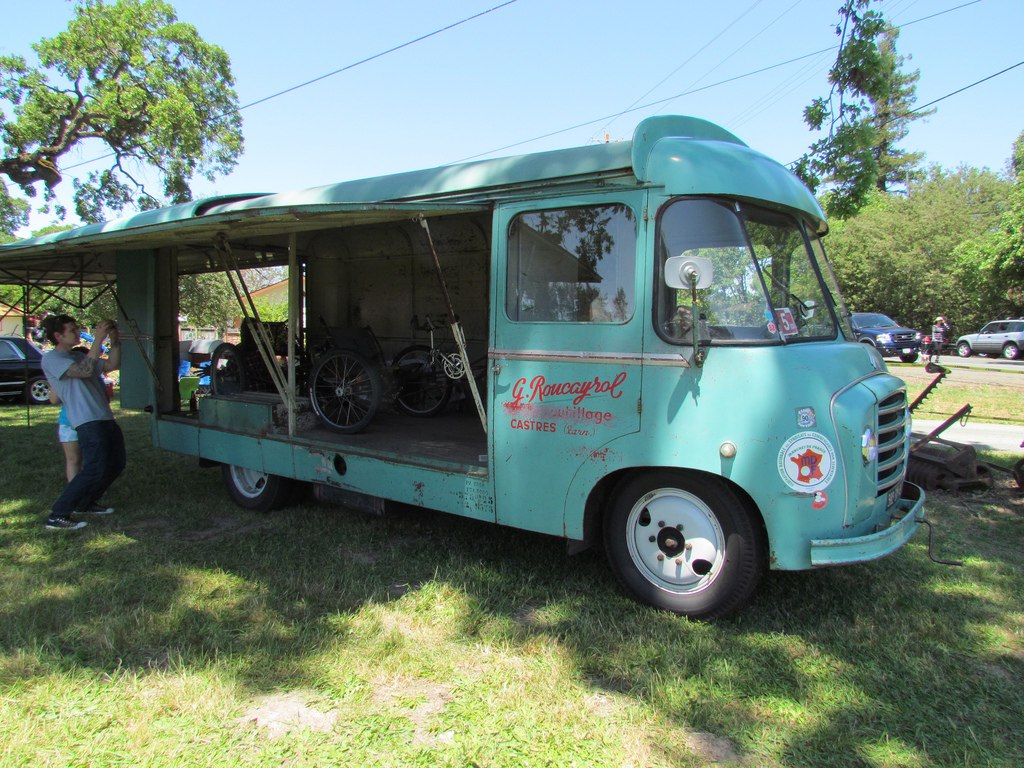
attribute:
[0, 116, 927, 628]
truck — blue